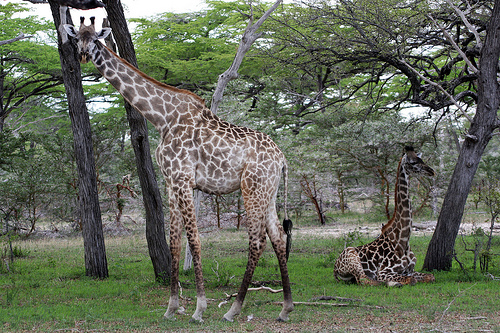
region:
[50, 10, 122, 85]
the head of a giraffe.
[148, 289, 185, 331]
right front giraffe leg.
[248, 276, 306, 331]
rear left giraffe leg.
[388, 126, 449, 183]
the head of a giraffe.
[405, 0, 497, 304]
a tall branch filled tree.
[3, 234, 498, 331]
a field of lush green grass.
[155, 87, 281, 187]
the body of a giraffe.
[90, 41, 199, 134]
long giraffe neck.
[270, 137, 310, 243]
the tail of a giraffe.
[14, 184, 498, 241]
a green park.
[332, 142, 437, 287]
A giraffe lying on the ground with its head up.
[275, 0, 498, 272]
A large tree tilting to the right with no leaves.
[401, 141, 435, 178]
Head of a giraffe that is mostly lying on the ground.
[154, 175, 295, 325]
Four legs of a standing giraffe.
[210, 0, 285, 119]
Thin gray branch sticking up behind a standing giraffes back.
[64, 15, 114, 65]
Head of a giraffe that is standing.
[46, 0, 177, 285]
Two brown trees behind a standing giraffe that lean to the left.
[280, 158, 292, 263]
Long tail of a standing giraffe.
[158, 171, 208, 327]
Two front legs of a standing giraffe.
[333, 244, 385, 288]
Back hind quarter of a giraffe that is sitting on the ground.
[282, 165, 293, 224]
tail on the giraffe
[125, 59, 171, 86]
hair on the giraffe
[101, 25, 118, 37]
an ear on giraffe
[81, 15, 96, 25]
horns on the giraffe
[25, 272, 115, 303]
patch of green grass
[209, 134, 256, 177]
spots on the giraffe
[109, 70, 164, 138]
neck on the giraffe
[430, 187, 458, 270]
trunk on the tree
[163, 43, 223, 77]
leaves on the tree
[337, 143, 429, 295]
elephant sitting on grass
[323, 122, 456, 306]
a giraffe sitting on the ground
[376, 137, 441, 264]
a giraffe with a long neck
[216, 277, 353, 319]
tree branches on the ground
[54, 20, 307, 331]
a giraffe standing up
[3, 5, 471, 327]
two giraffes in the wild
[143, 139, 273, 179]
a pattern of spots on a giraffe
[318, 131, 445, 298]
a giraffe on the ground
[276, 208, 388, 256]
a patch of sand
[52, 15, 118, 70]
two horns on a giraffe's head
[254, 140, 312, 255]
a long giraffe tail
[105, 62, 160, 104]
neck of the giraffe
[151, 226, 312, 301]
legs of the giraffe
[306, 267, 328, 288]
grass under the giraffe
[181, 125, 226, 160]
brown spots on giraffe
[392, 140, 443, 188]
head of the animal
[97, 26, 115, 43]
ear of the animal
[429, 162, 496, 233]
branch of the tree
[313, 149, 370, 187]
trees in the distance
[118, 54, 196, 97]
hair on the giraffe's neck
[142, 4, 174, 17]
sky above the trees